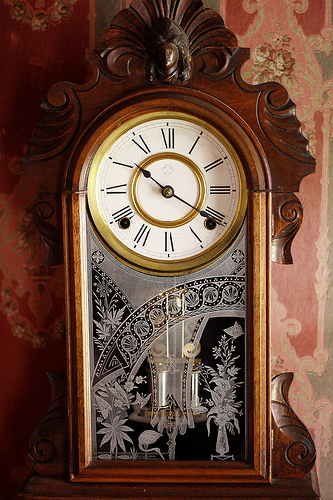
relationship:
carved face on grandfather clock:
[147, 17, 194, 85] [19, 0, 321, 499]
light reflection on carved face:
[163, 50, 174, 65] [159, 39, 180, 69]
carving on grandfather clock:
[93, 0, 239, 86] [19, 0, 321, 499]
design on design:
[97, 252, 238, 456] [97, 252, 238, 456]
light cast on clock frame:
[259, 216, 269, 384] [250, 171, 275, 478]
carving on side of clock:
[271, 367, 315, 475] [83, 121, 261, 275]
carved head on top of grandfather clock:
[146, 15, 192, 81] [19, 0, 321, 499]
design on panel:
[97, 252, 238, 456] [82, 218, 248, 462]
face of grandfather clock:
[94, 118, 242, 262] [19, 0, 321, 499]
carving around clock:
[44, 30, 317, 171] [78, 114, 283, 271]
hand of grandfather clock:
[133, 162, 162, 189] [19, 0, 321, 499]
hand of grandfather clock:
[171, 194, 216, 223] [19, 0, 321, 499]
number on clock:
[159, 123, 177, 149] [63, 90, 262, 274]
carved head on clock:
[146, 15, 190, 81] [68, 85, 267, 478]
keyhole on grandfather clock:
[119, 216, 130, 229] [19, 0, 321, 499]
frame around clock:
[87, 106, 244, 276] [53, 114, 310, 471]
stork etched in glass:
[138, 430, 164, 459] [86, 216, 249, 461]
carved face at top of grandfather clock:
[159, 39, 180, 69] [19, 0, 321, 499]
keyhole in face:
[202, 216, 217, 230] [85, 118, 241, 278]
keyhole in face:
[117, 215, 132, 230] [85, 118, 241, 278]